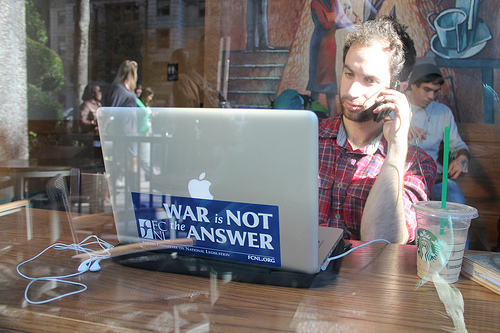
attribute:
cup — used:
[408, 130, 482, 290]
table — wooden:
[1, 210, 461, 325]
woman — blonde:
[79, 79, 106, 144]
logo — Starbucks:
[405, 218, 440, 288]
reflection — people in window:
[8, 19, 350, 331]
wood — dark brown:
[124, 281, 302, 331]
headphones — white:
[34, 241, 151, 309]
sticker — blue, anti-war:
[130, 192, 280, 269]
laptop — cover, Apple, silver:
[95, 93, 349, 287]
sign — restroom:
[166, 60, 178, 81]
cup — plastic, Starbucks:
[392, 122, 497, 304]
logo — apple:
[172, 169, 223, 204]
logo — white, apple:
[182, 170, 212, 204]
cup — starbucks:
[405, 192, 485, 290]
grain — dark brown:
[228, 290, 345, 330]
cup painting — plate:
[418, 1, 498, 68]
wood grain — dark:
[327, 261, 498, 331]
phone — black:
[382, 72, 404, 120]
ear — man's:
[384, 72, 400, 94]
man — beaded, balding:
[313, 15, 437, 251]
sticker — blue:
[121, 177, 291, 274]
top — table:
[3, 200, 453, 323]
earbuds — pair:
[1, 205, 133, 330]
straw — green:
[431, 114, 461, 244]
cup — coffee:
[418, 4, 478, 58]